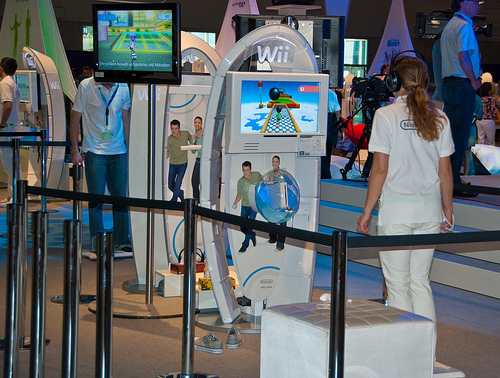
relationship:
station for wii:
[191, 23, 445, 330] [255, 182, 290, 213]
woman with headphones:
[360, 50, 457, 330] [383, 50, 427, 95]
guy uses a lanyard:
[70, 75, 134, 259] [97, 80, 119, 128]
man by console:
[0, 57, 24, 205] [16, 119, 37, 147]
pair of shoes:
[3, 195, 18, 208] [3, 197, 17, 207]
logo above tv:
[257, 43, 291, 65] [226, 66, 329, 157]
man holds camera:
[433, 14, 453, 188] [412, 10, 491, 41]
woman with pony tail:
[360, 50, 457, 330] [402, 79, 447, 140]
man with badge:
[70, 75, 134, 259] [99, 127, 114, 141]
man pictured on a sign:
[164, 120, 195, 200] [126, 28, 221, 295]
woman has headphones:
[360, 50, 457, 330] [383, 50, 427, 95]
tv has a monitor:
[92, 1, 180, 82] [91, 0, 182, 88]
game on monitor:
[226, 66, 329, 157] [236, 75, 317, 151]